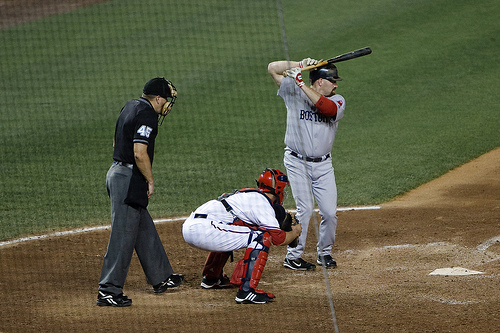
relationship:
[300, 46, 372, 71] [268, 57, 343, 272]
bat in hands of batter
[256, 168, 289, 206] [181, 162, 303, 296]
helmet on catcher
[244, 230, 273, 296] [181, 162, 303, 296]
knee guard on catcher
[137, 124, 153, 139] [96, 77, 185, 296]
number on umpire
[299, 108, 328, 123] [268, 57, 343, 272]
team name on shirt of batter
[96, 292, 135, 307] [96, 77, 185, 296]
sneaker on umpire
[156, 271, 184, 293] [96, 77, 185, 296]
sneaker on umpire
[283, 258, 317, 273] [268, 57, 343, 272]
shoe on batter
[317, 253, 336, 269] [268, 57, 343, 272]
shoe on batter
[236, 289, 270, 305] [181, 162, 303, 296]
shoe on catcher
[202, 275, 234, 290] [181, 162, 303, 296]
shoe on catcher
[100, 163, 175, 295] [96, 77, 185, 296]
pants of umpire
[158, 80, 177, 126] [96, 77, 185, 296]
faceguard on umpire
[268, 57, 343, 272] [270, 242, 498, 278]
batter in box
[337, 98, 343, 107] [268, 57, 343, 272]
logo on batter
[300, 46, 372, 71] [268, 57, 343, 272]
bat being held by batter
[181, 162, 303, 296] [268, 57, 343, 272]
catcher behind batter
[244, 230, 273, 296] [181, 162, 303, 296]
knee guard being worn by catcher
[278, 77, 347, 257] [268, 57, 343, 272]
uniform on batter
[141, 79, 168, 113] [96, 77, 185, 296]
head of umpire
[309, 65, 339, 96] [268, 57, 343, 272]
head of batter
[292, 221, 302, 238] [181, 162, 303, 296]
hand of catcher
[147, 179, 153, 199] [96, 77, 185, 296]
hand of umpire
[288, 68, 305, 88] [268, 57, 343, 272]
hand of batter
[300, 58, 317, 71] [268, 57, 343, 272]
hand of batter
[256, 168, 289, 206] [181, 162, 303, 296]
helmet worn bu catcher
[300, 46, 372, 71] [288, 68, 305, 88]
bat in hand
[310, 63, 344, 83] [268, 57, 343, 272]
helmet on batter